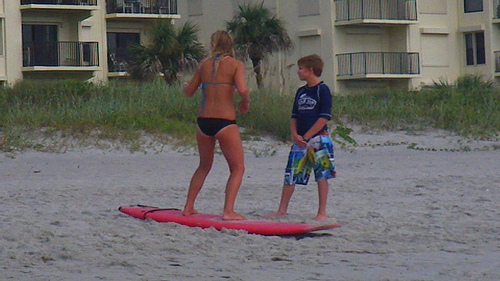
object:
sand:
[0, 138, 499, 281]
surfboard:
[117, 203, 342, 236]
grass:
[0, 72, 499, 158]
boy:
[261, 51, 335, 220]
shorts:
[280, 132, 340, 187]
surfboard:
[105, 180, 351, 249]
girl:
[177, 29, 254, 221]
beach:
[3, 135, 498, 280]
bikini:
[192, 55, 237, 139]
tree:
[218, 0, 299, 96]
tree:
[117, 11, 209, 89]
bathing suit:
[195, 115, 239, 138]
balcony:
[15, 42, 100, 73]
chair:
[107, 53, 131, 74]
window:
[460, 31, 484, 66]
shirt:
[290, 80, 334, 141]